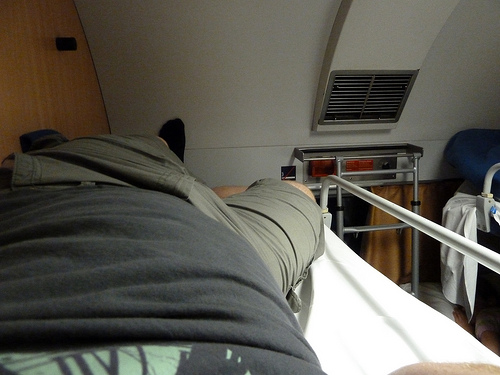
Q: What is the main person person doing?
A: Laying down.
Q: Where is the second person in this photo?
A: In the lower right corner.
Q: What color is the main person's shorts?
A: Green.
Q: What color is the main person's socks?
A: Black.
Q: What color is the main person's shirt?
A: Gray.